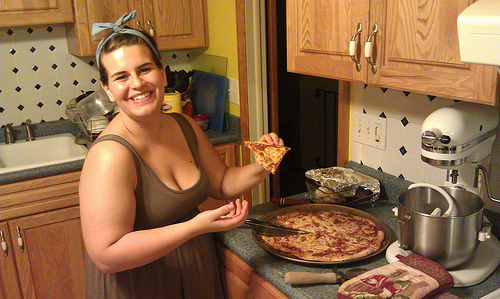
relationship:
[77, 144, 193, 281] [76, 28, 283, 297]
arm on woman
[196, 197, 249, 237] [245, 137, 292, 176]
hand with a slice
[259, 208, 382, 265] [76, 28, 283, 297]
pizza by woman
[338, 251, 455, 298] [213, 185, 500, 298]
mitt on counter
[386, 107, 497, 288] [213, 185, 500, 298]
mixer on counter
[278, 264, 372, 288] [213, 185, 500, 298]
cutter on counter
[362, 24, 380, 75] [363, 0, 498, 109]
handle on cabinet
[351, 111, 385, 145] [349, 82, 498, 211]
outlet on wall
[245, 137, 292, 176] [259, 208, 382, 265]
slice of pizza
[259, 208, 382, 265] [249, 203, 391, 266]
pizza on pan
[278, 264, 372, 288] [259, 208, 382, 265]
cutter for pizza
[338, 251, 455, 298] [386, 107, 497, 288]
mitt by mixer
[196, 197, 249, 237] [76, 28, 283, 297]
hand on woman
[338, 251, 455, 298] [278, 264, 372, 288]
mitt over cutter